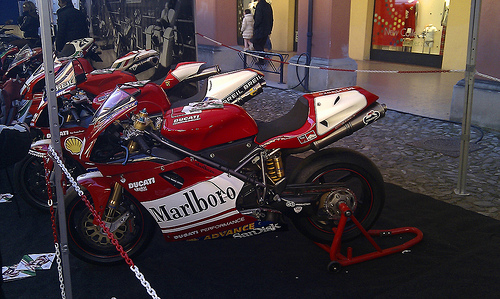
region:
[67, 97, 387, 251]
a Marlboro motorcycle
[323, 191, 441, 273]
a red bike stand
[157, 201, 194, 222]
black letters on a white background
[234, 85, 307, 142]
black seat on a motorcycle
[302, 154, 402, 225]
a wheel on a motorcycle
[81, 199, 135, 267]
a red chain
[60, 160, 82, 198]
a white metal chain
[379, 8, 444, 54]
a window display in a store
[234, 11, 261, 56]
a person wearing whit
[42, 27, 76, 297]
a metal pole in a building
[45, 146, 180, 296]
a red and white metal chain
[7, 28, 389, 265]
Some motorcycles all lined up in a row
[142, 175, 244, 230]
A corporate sponsor ad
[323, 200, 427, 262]
A red metal rack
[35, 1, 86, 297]
A gray metal pole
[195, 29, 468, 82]
Another red and white chain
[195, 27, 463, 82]
The chain is made of metal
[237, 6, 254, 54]
A person walking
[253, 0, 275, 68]
A person in a black coat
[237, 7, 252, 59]
The person is wearing a white coat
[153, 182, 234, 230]
the bikes says marlboro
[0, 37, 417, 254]
the bikes are red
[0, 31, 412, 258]
the bikes are parked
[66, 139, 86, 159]
the bike has a shell logo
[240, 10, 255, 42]
the girl has a white coat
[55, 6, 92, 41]
the person has a black jacket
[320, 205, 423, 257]
the bike is on a stand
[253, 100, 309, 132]
the seat is black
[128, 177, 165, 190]
the brand is ducati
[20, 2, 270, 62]
people are walking by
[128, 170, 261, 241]
marlboro written on motorcycle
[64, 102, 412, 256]
red and white motorcycle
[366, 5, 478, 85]
shop window display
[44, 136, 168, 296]
red and white chain around the motorcycles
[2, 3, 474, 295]
motorcycles are inside the mall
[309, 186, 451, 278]
motorcycle on a red stand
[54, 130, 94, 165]
yellow shell logo on side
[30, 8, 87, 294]
metal pole holding chain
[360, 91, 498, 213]
rock cobblestone path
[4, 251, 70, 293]
two green and white booklets on the ground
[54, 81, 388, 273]
a motorbike parked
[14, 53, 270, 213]
a motorbike parked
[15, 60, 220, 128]
a motorbike parked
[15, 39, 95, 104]
a motorbike parked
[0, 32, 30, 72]
a motorbike parked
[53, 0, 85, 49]
a person standing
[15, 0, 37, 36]
a person standing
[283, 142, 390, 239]
a motorbike wheel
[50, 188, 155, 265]
a motorbike wheel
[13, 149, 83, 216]
a motorbike wheel